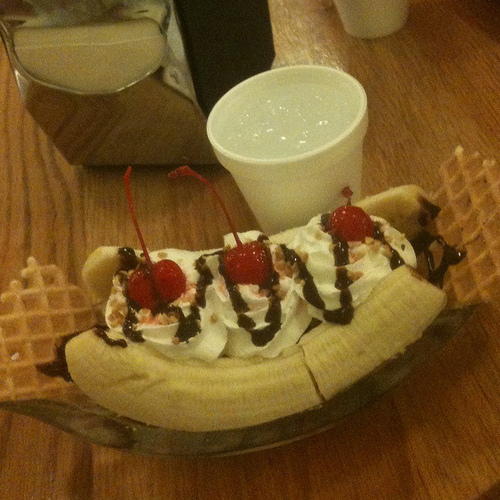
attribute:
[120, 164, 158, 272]
stem — red, small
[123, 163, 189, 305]
cherry — red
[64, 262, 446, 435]
banana — long, broken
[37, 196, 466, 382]
chocolate sauce — brown, zig zagged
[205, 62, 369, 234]
cup — white, styrofoam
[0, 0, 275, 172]
napkin holder — silver, chrome, black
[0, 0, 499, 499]
table — wooden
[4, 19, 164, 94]
paper nakins — white